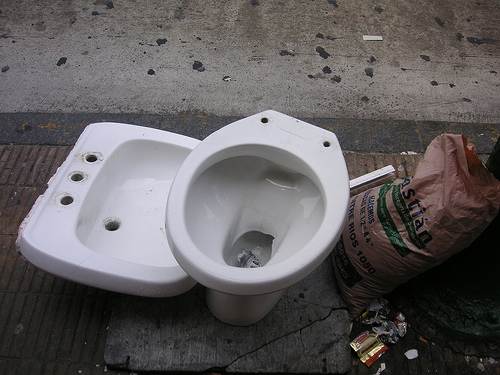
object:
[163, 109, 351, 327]
toilet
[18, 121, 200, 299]
sink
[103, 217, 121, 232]
drain hole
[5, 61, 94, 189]
pavement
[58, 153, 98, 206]
three holes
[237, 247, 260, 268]
gray object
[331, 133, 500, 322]
brown bag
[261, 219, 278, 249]
crack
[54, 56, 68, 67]
black spot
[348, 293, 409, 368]
litter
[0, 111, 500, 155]
dark line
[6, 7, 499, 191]
sidewalk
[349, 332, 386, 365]
plastic cover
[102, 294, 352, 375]
cement block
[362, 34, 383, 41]
white paper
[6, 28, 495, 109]
street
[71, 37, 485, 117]
road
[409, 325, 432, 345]
electrical wiring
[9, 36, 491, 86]
concrete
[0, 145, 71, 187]
grate pattern